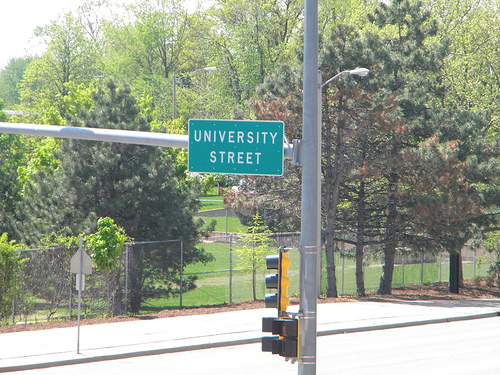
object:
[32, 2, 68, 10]
sky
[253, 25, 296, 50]
tree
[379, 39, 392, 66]
leaves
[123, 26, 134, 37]
trees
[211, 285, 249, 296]
grass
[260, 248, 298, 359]
traffic light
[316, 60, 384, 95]
street lamp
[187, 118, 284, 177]
street sign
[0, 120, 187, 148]
pole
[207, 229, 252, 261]
fence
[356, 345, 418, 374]
street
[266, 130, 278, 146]
white letters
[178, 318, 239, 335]
sidewalk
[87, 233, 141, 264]
ivy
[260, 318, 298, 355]
walk signs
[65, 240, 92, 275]
school sign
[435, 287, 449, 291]
pinstraw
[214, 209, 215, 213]
parking lot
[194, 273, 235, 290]
walking track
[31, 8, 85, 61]
roof